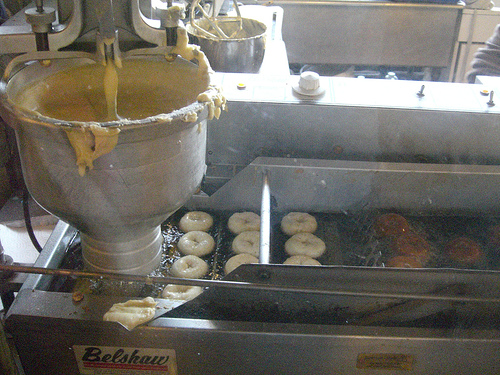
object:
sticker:
[353, 346, 418, 373]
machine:
[0, 0, 500, 374]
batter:
[41, 73, 154, 115]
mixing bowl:
[0, 41, 227, 296]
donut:
[180, 210, 213, 233]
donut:
[226, 210, 261, 234]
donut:
[281, 207, 318, 236]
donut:
[231, 230, 264, 253]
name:
[74, 343, 177, 375]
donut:
[393, 234, 438, 256]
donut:
[444, 237, 480, 265]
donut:
[376, 211, 409, 236]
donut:
[391, 254, 419, 268]